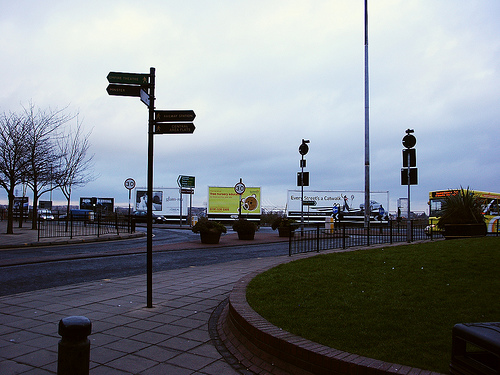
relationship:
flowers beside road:
[194, 213, 313, 243] [0, 214, 441, 302]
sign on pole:
[152, 109, 197, 124] [144, 63, 156, 308]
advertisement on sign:
[212, 192, 231, 211] [205, 183, 263, 216]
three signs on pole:
[262, 122, 369, 226] [300, 155, 304, 233]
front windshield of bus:
[428, 196, 448, 213] [422, 186, 500, 236]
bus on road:
[422, 186, 500, 236] [0, 223, 442, 293]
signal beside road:
[401, 129, 418, 185] [0, 214, 441, 302]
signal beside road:
[298, 141, 308, 185] [0, 214, 441, 302]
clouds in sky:
[50, 14, 422, 154] [7, 3, 488, 215]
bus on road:
[420, 171, 497, 235] [144, 200, 191, 235]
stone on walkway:
[100, 351, 168, 375] [1, 234, 453, 374]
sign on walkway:
[152, 109, 197, 124] [77, 275, 229, 374]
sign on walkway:
[102, 66, 149, 84] [77, 275, 229, 374]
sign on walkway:
[155, 102, 204, 125] [77, 275, 229, 374]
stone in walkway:
[10, 344, 57, 369] [0, 244, 296, 373]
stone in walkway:
[100, 351, 168, 375] [0, 244, 296, 373]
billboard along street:
[205, 185, 262, 215] [1, 219, 424, 295]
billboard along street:
[285, 187, 390, 219] [1, 219, 424, 295]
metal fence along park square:
[284, 220, 471, 257] [207, 227, 499, 373]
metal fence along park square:
[28, 212, 139, 243] [207, 227, 499, 373]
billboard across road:
[205, 183, 262, 215] [0, 232, 446, 302]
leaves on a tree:
[31, 169, 55, 180] [2, 102, 72, 234]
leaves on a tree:
[14, 155, 27, 170] [2, 102, 72, 234]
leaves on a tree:
[0, 159, 10, 176] [2, 102, 72, 234]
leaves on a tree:
[8, 130, 15, 138] [2, 102, 72, 234]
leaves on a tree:
[38, 149, 48, 155] [2, 102, 72, 234]